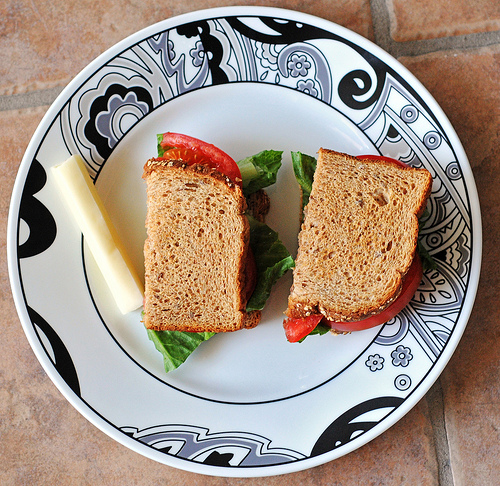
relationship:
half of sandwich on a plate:
[281, 145, 435, 344] [8, 7, 487, 476]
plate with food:
[8, 7, 487, 476] [50, 132, 433, 373]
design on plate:
[92, 16, 419, 87] [8, 7, 487, 476]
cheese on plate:
[50, 157, 146, 318] [8, 7, 487, 476]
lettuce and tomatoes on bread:
[159, 130, 290, 313] [144, 160, 246, 334]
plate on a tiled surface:
[8, 7, 487, 476] [2, 0, 499, 485]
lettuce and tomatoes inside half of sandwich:
[159, 130, 243, 192] [144, 132, 294, 371]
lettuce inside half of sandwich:
[243, 147, 318, 304] [281, 145, 435, 344]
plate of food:
[8, 7, 487, 476] [50, 132, 433, 373]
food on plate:
[50, 132, 433, 373] [8, 7, 487, 476]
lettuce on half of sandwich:
[243, 147, 318, 304] [281, 145, 435, 344]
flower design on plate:
[289, 55, 312, 79] [8, 7, 487, 476]